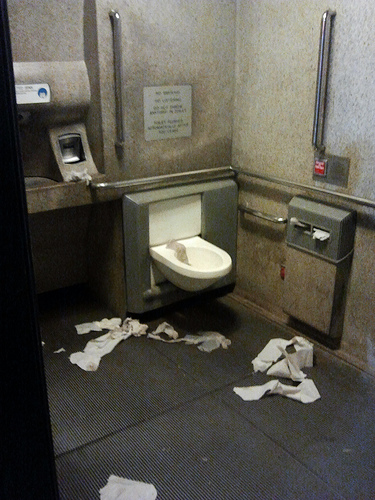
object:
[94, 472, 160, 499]
paper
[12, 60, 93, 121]
dryer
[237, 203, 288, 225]
handrail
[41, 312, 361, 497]
floor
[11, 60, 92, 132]
tissue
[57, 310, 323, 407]
toilet paper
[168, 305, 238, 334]
shadow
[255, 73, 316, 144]
wall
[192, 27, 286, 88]
wall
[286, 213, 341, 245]
toilet paper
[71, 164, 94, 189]
toilet paper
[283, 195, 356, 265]
dispenser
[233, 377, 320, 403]
trash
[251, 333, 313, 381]
trash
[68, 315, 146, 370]
trash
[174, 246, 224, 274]
bowl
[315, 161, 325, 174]
sign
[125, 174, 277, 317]
toilet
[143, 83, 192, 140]
sign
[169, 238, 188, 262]
tissue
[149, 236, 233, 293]
commode bowl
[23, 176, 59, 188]
basin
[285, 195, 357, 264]
box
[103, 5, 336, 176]
bars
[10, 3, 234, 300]
wall